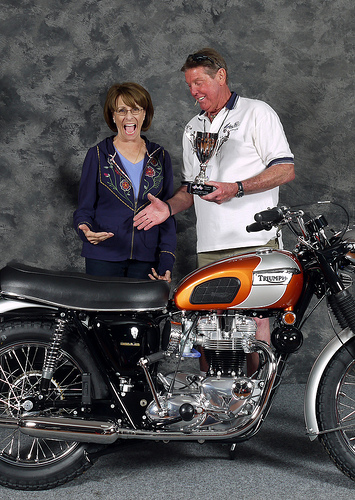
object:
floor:
[0, 375, 355, 499]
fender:
[302, 326, 355, 422]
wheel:
[318, 339, 355, 478]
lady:
[70, 80, 181, 284]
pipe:
[15, 335, 286, 443]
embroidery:
[94, 147, 169, 222]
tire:
[315, 329, 355, 479]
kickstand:
[228, 440, 240, 454]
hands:
[132, 190, 174, 233]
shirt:
[179, 91, 296, 257]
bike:
[0, 196, 355, 495]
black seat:
[0, 255, 173, 314]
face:
[184, 67, 220, 113]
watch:
[234, 180, 245, 200]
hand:
[199, 176, 236, 207]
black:
[186, 275, 241, 309]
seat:
[0, 260, 169, 313]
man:
[129, 48, 296, 380]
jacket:
[71, 135, 177, 277]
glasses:
[111, 106, 146, 116]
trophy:
[181, 124, 223, 207]